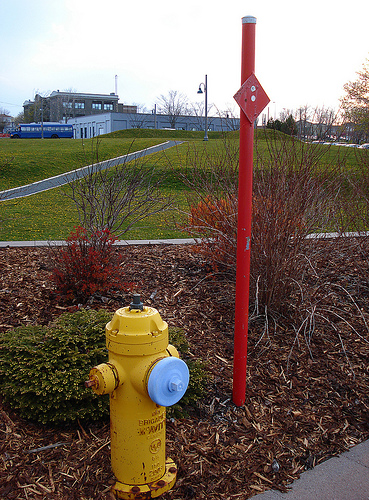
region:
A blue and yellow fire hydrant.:
[80, 296, 188, 492]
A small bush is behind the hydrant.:
[0, 308, 212, 427]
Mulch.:
[227, 375, 314, 467]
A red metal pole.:
[204, 9, 271, 396]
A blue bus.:
[4, 111, 71, 138]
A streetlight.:
[190, 59, 208, 137]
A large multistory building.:
[18, 85, 136, 122]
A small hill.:
[24, 118, 358, 193]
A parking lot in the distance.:
[304, 124, 360, 153]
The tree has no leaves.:
[150, 83, 187, 127]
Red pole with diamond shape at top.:
[226, 16, 273, 406]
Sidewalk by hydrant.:
[241, 438, 365, 498]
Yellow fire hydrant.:
[84, 294, 195, 499]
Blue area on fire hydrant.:
[143, 356, 193, 409]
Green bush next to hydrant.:
[3, 307, 215, 430]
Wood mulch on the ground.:
[1, 235, 365, 496]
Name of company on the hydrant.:
[133, 407, 169, 478]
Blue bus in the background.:
[7, 118, 74, 140]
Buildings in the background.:
[1, 86, 360, 142]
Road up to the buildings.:
[2, 136, 195, 204]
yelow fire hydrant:
[95, 291, 183, 463]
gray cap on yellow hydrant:
[147, 354, 189, 406]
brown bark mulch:
[13, 436, 98, 488]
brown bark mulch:
[188, 428, 298, 473]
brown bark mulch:
[269, 339, 351, 428]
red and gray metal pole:
[237, 39, 260, 249]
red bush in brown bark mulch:
[59, 225, 131, 290]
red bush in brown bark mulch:
[266, 155, 327, 345]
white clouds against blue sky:
[26, 15, 204, 67]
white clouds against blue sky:
[278, 25, 326, 89]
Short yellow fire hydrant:
[85, 292, 192, 498]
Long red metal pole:
[226, 15, 259, 410]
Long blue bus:
[8, 122, 74, 140]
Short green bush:
[1, 306, 211, 426]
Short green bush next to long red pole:
[1, 303, 215, 427]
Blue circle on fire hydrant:
[144, 354, 189, 408]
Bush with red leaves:
[44, 222, 140, 307]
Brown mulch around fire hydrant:
[0, 236, 366, 496]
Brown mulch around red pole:
[0, 233, 366, 497]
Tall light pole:
[197, 71, 209, 141]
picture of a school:
[11, 36, 368, 279]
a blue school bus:
[5, 109, 94, 156]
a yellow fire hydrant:
[30, 252, 221, 498]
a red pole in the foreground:
[200, 3, 308, 319]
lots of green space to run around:
[17, 135, 368, 249]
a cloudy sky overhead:
[8, 7, 360, 142]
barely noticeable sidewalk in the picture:
[114, 319, 367, 498]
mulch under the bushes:
[8, 250, 359, 487]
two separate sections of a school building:
[19, 83, 266, 142]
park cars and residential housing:
[295, 98, 368, 158]